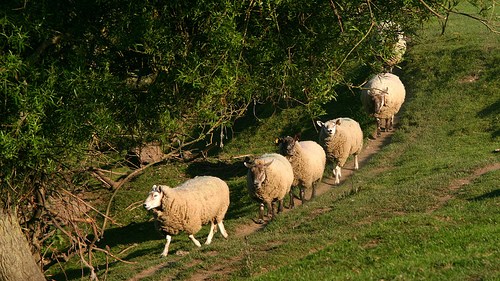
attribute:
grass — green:
[348, 188, 493, 278]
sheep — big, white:
[143, 175, 228, 255]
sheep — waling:
[140, 170, 242, 260]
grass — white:
[6, 4, 497, 279]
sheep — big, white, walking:
[143, 119, 395, 211]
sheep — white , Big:
[137, 173, 232, 247]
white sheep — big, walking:
[142, 172, 231, 257]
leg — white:
[153, 231, 185, 266]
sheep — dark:
[242, 152, 293, 218]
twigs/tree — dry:
[24, 184, 113, 275]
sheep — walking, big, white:
[100, 110, 390, 260]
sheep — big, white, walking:
[135, 170, 236, 256]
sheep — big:
[135, 162, 238, 263]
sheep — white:
[129, 62, 423, 262]